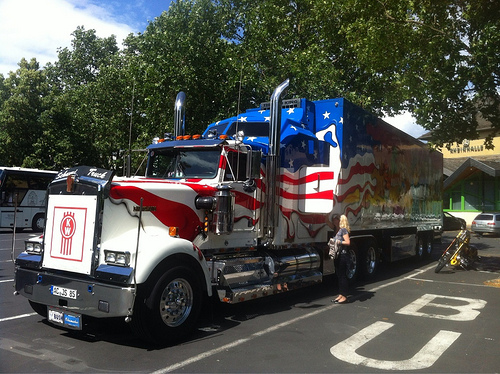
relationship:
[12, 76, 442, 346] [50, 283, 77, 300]
semi truck has tag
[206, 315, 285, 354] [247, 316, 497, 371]
line on ground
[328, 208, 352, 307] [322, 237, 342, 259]
woman holding something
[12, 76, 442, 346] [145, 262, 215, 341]
semi truck has tire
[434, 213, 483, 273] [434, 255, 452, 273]
motorcycle has tire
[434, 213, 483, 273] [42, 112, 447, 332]
motorcycle parked near truck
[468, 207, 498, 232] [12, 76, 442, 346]
car near semi truck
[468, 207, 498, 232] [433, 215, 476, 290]
car near motorcycle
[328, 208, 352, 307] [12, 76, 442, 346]
woman standing next to semi truck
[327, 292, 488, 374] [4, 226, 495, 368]
letters on ground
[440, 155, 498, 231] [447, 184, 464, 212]
building has pillars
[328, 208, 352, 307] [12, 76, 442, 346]
woman standing by semi truck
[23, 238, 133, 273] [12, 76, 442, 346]
headlights on semi truck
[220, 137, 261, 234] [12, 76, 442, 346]
door on semi truck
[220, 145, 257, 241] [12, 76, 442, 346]
door on semi truck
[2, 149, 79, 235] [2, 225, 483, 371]
bus in parking lot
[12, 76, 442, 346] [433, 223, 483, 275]
semi truck parked by motorcycle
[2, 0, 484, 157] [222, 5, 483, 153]
leaves on trees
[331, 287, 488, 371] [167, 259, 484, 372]
letters on cement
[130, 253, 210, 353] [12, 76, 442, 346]
tire on semi truck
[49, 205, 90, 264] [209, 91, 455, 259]
flag on semi-trailer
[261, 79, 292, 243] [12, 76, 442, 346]
exhaust pipe on semi truck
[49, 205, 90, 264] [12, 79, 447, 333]
flag on truck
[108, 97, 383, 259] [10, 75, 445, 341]
flag on 18 wheeler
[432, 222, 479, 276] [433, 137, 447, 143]
motorcycle on ground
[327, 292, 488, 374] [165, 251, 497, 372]
letters on parking lot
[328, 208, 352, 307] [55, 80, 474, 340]
woman checking truck